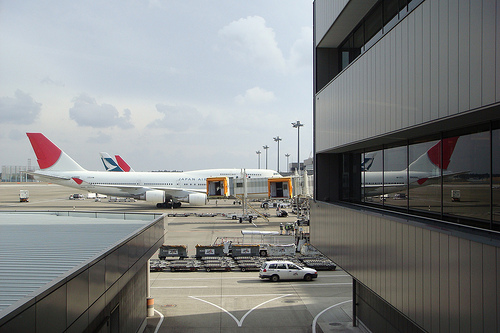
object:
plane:
[24, 132, 283, 205]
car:
[257, 259, 318, 282]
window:
[440, 130, 493, 229]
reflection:
[356, 135, 499, 207]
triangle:
[186, 292, 291, 325]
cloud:
[68, 93, 135, 132]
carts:
[158, 244, 188, 260]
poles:
[294, 127, 302, 177]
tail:
[101, 154, 122, 173]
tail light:
[263, 269, 266, 272]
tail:
[114, 153, 135, 171]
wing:
[27, 172, 206, 203]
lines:
[148, 281, 354, 290]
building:
[0, 211, 165, 331]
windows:
[340, 24, 362, 71]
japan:
[178, 178, 195, 181]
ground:
[0, 181, 368, 331]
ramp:
[205, 177, 290, 197]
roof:
[0, 210, 164, 322]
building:
[312, 0, 499, 333]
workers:
[279, 223, 284, 235]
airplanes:
[25, 132, 285, 209]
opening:
[208, 178, 227, 198]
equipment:
[17, 189, 31, 201]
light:
[291, 121, 305, 173]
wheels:
[174, 201, 182, 208]